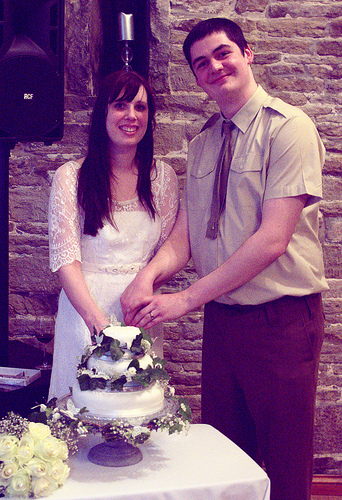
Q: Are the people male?
A: No, they are both male and female.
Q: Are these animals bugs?
A: Yes, all the animals are bugs.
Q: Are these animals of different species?
A: No, all the animals are bugs.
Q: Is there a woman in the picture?
A: Yes, there is a woman.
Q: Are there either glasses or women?
A: Yes, there is a woman.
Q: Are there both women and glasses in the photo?
A: No, there is a woman but no glasses.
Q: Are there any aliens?
A: No, there are no aliens.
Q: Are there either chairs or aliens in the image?
A: No, there are no aliens or chairs.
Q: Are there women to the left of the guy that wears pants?
A: Yes, there is a woman to the left of the guy.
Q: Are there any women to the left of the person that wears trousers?
A: Yes, there is a woman to the left of the guy.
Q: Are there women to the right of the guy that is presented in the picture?
A: No, the woman is to the left of the guy.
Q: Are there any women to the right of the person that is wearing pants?
A: No, the woman is to the left of the guy.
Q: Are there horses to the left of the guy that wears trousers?
A: No, there is a woman to the left of the guy.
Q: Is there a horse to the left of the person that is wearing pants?
A: No, there is a woman to the left of the guy.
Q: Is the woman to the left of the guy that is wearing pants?
A: Yes, the woman is to the left of the guy.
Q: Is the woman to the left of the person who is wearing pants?
A: Yes, the woman is to the left of the guy.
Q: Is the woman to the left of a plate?
A: No, the woman is to the left of the guy.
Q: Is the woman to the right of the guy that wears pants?
A: No, the woman is to the left of the guy.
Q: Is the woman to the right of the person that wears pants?
A: No, the woman is to the left of the guy.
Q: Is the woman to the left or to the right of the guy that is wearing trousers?
A: The woman is to the left of the guy.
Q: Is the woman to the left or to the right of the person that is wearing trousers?
A: The woman is to the left of the guy.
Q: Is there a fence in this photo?
A: No, there are no fences.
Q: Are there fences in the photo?
A: No, there are no fences.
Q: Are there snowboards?
A: No, there are no snowboards.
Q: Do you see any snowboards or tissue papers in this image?
A: No, there are no snowboards or tissue papers.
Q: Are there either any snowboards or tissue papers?
A: No, there are no snowboards or tissue papers.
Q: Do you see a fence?
A: No, there are no fences.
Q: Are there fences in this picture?
A: No, there are no fences.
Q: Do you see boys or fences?
A: No, there are no fences or boys.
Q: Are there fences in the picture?
A: No, there are no fences.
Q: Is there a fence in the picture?
A: No, there are no fences.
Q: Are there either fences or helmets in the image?
A: No, there are no fences or helmets.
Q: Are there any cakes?
A: Yes, there is a cake.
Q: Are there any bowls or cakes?
A: Yes, there is a cake.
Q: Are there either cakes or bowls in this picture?
A: Yes, there is a cake.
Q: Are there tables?
A: Yes, there is a table.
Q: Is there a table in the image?
A: Yes, there is a table.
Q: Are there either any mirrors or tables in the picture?
A: Yes, there is a table.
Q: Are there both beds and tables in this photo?
A: No, there is a table but no beds.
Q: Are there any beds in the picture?
A: No, there are no beds.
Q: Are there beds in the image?
A: No, there are no beds.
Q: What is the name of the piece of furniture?
A: The piece of furniture is a table.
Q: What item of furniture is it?
A: The piece of furniture is a table.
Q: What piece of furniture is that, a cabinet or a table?
A: That is a table.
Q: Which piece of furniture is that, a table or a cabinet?
A: That is a table.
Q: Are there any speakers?
A: Yes, there is a speaker.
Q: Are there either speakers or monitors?
A: Yes, there is a speaker.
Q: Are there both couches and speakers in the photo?
A: No, there is a speaker but no couches.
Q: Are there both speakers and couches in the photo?
A: No, there is a speaker but no couches.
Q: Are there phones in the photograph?
A: No, there are no phones.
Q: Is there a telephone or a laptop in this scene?
A: No, there are no phones or laptops.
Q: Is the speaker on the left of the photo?
A: Yes, the speaker is on the left of the image.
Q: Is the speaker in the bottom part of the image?
A: No, the speaker is in the top of the image.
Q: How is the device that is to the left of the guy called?
A: The device is a speaker.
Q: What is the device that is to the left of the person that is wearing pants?
A: The device is a speaker.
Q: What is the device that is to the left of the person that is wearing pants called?
A: The device is a speaker.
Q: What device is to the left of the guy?
A: The device is a speaker.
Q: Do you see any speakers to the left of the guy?
A: Yes, there is a speaker to the left of the guy.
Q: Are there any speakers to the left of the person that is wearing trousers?
A: Yes, there is a speaker to the left of the guy.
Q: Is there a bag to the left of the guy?
A: No, there is a speaker to the left of the guy.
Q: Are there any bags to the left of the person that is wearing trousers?
A: No, there is a speaker to the left of the guy.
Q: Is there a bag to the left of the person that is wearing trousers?
A: No, there is a speaker to the left of the guy.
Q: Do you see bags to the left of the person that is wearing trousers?
A: No, there is a speaker to the left of the guy.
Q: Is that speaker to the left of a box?
A: No, the speaker is to the left of the guy.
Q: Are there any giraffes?
A: No, there are no giraffes.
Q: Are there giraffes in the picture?
A: No, there are no giraffes.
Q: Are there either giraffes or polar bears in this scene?
A: No, there are no giraffes or polar bears.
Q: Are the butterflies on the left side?
A: Yes, the butterflies are on the left of the image.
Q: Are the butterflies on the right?
A: No, the butterflies are on the left of the image.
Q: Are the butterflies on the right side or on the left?
A: The butterflies are on the left of the image.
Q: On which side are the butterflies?
A: The butterflies are on the left of the image.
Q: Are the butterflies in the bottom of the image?
A: Yes, the butterflies are in the bottom of the image.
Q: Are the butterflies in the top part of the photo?
A: No, the butterflies are in the bottom of the image.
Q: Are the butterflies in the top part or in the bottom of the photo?
A: The butterflies are in the bottom of the image.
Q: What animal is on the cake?
A: The butterflies are on the cake.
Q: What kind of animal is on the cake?
A: The animals are butterflies.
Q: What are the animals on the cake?
A: The animals are butterflies.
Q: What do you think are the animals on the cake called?
A: The animals are butterflies.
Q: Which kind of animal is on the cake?
A: The animals are butterflies.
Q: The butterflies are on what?
A: The butterflies are on the cake.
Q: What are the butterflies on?
A: The butterflies are on the cake.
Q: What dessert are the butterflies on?
A: The butterflies are on the cake.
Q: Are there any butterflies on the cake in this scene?
A: Yes, there are butterflies on the cake.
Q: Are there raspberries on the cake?
A: No, there are butterflies on the cake.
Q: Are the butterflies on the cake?
A: Yes, the butterflies are on the cake.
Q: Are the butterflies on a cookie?
A: No, the butterflies are on the cake.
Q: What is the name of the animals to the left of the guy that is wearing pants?
A: The animals are butterflies.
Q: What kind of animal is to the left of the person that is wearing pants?
A: The animals are butterflies.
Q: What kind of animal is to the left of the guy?
A: The animals are butterflies.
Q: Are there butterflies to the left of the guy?
A: Yes, there are butterflies to the left of the guy.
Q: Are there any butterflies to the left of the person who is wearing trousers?
A: Yes, there are butterflies to the left of the guy.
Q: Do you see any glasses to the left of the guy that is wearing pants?
A: No, there are butterflies to the left of the guy.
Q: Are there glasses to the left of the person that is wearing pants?
A: No, there are butterflies to the left of the guy.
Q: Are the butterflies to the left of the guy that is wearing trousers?
A: Yes, the butterflies are to the left of the guy.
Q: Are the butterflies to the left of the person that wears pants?
A: Yes, the butterflies are to the left of the guy.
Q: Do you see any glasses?
A: No, there are no glasses.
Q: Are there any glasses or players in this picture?
A: No, there are no glasses or players.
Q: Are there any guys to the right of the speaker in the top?
A: Yes, there is a guy to the right of the speaker.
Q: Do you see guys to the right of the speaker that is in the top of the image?
A: Yes, there is a guy to the right of the speaker.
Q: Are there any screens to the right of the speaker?
A: No, there is a guy to the right of the speaker.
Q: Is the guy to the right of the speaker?
A: Yes, the guy is to the right of the speaker.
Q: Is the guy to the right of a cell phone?
A: No, the guy is to the right of the speaker.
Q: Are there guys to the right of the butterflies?
A: Yes, there is a guy to the right of the butterflies.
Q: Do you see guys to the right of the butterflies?
A: Yes, there is a guy to the right of the butterflies.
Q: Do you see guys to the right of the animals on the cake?
A: Yes, there is a guy to the right of the butterflies.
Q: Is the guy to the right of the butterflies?
A: Yes, the guy is to the right of the butterflies.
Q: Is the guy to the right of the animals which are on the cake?
A: Yes, the guy is to the right of the butterflies.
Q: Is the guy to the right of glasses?
A: No, the guy is to the right of the butterflies.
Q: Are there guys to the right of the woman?
A: Yes, there is a guy to the right of the woman.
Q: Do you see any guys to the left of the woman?
A: No, the guy is to the right of the woman.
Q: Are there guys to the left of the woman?
A: No, the guy is to the right of the woman.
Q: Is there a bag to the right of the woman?
A: No, there is a guy to the right of the woman.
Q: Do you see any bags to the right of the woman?
A: No, there is a guy to the right of the woman.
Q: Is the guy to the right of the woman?
A: Yes, the guy is to the right of the woman.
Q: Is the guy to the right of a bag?
A: No, the guy is to the right of the woman.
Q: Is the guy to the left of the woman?
A: No, the guy is to the right of the woman.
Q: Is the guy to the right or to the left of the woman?
A: The guy is to the right of the woman.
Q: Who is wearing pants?
A: The guy is wearing pants.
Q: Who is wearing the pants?
A: The guy is wearing pants.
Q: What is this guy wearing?
A: The guy is wearing trousers.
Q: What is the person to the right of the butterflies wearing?
A: The guy is wearing trousers.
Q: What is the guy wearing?
A: The guy is wearing trousers.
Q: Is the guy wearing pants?
A: Yes, the guy is wearing pants.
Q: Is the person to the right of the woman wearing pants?
A: Yes, the guy is wearing pants.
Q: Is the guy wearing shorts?
A: No, the guy is wearing pants.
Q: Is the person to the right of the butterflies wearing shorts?
A: No, the guy is wearing pants.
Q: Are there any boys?
A: No, there are no boys.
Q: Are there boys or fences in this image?
A: No, there are no boys or fences.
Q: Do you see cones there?
A: No, there are no cones.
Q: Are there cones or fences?
A: No, there are no cones or fences.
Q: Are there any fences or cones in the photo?
A: No, there are no cones or fences.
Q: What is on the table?
A: The rose is on the table.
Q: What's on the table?
A: The rose is on the table.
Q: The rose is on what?
A: The rose is on the table.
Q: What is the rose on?
A: The rose is on the table.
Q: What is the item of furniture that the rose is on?
A: The piece of furniture is a table.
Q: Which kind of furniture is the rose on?
A: The rose is on the table.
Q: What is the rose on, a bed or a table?
A: The rose is on a table.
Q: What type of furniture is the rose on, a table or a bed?
A: The rose is on a table.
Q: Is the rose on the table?
A: Yes, the rose is on the table.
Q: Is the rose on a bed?
A: No, the rose is on the table.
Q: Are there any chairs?
A: No, there are no chairs.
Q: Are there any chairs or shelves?
A: No, there are no chairs or shelves.